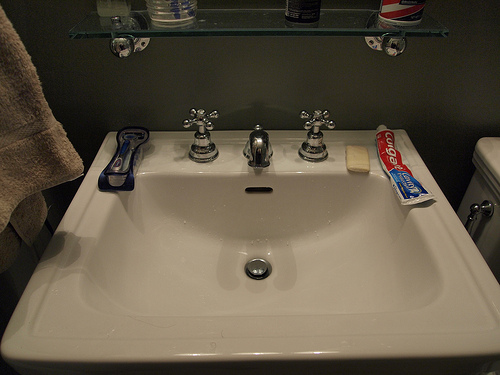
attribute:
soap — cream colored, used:
[341, 146, 382, 187]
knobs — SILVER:
[296, 109, 335, 161]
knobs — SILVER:
[183, 105, 220, 163]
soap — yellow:
[341, 139, 374, 183]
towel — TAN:
[6, 39, 39, 184]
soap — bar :
[342, 140, 374, 172]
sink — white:
[2, 102, 497, 373]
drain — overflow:
[244, 186, 273, 194]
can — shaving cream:
[370, 0, 436, 28]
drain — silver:
[243, 253, 270, 280]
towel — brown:
[4, 9, 94, 256]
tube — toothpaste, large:
[374, 122, 434, 205]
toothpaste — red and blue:
[375, 124, 438, 209]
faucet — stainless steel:
[173, 107, 344, 176]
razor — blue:
[114, 124, 140, 179]